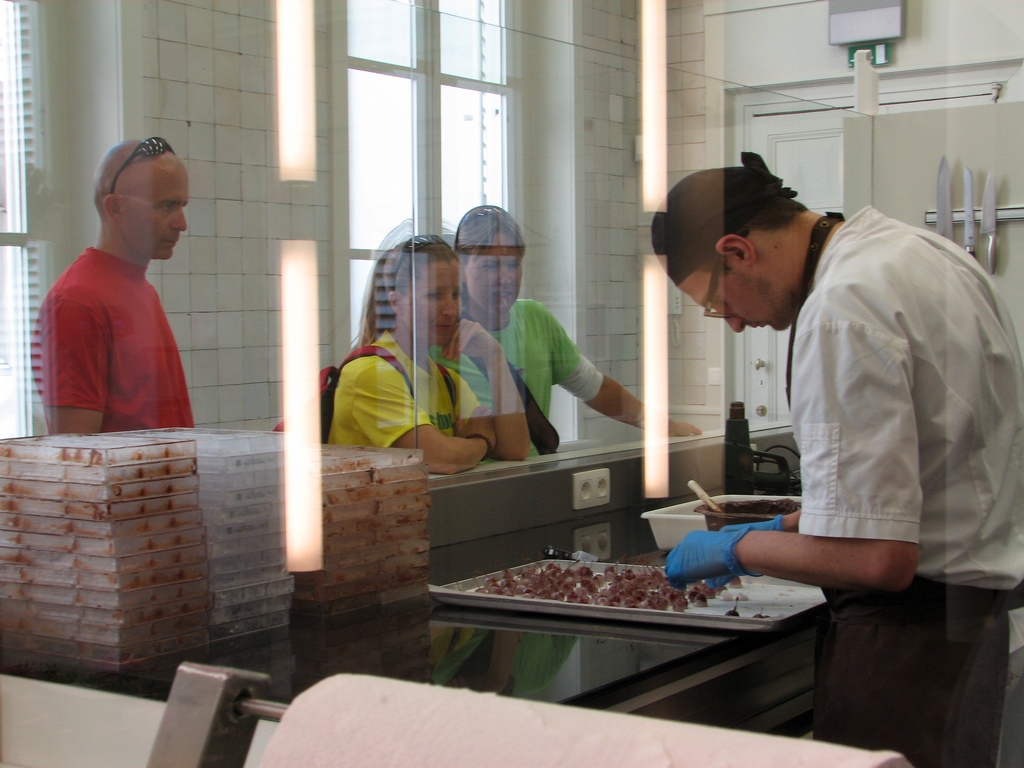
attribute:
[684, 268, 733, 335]
sunglasses — black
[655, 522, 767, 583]
glove — blue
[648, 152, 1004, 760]
man — bald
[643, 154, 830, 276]
head wrap — black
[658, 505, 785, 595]
gloves — blue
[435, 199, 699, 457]
woman — brown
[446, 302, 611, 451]
shirt — haired, green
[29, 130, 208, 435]
man — bald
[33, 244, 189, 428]
shirt — red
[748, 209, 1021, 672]
apron — black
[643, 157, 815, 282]
head wrap — black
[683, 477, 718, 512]
handle — white